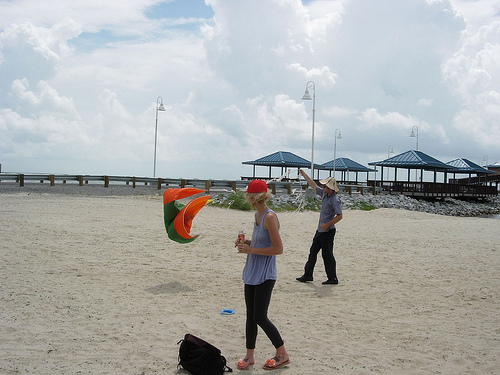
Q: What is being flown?
A: Kite.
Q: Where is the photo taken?
A: Beach.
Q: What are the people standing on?
A: Sand.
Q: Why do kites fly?
A: Wind.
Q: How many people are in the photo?
A: Two.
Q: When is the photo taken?
A: Daytime.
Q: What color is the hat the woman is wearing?
A: Red.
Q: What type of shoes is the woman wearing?
A: Sandals.